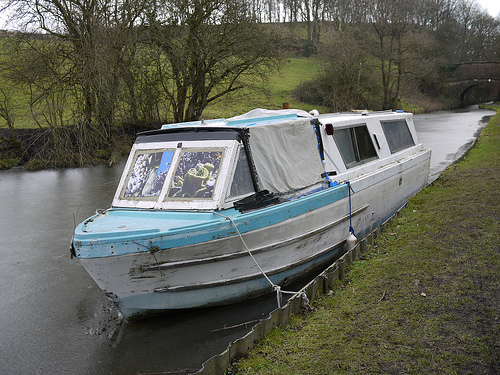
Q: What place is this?
A: It is a shore.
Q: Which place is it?
A: It is a shore.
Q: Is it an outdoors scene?
A: Yes, it is outdoors.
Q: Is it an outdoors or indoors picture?
A: It is outdoors.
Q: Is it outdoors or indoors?
A: It is outdoors.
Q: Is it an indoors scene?
A: No, it is outdoors.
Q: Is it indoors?
A: No, it is outdoors.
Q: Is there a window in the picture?
A: Yes, there is a window.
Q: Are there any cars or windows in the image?
A: Yes, there is a window.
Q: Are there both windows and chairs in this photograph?
A: No, there is a window but no chairs.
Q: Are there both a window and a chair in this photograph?
A: No, there is a window but no chairs.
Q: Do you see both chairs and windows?
A: No, there is a window but no chairs.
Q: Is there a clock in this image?
A: No, there are no clocks.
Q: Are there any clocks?
A: No, there are no clocks.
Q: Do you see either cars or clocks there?
A: No, there are no clocks or cars.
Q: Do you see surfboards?
A: No, there are no surfboards.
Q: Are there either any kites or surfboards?
A: No, there are no surfboards or kites.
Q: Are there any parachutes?
A: No, there are no parachutes.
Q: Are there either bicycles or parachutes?
A: No, there are no parachutes or bicycles.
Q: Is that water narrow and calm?
A: Yes, the water is narrow and calm.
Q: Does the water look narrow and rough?
A: No, the water is narrow but calm.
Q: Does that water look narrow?
A: Yes, the water is narrow.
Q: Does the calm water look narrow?
A: Yes, the water is narrow.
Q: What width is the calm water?
A: The water is narrow.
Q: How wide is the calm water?
A: The water is narrow.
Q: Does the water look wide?
A: No, the water is narrow.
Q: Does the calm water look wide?
A: No, the water is narrow.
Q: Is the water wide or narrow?
A: The water is narrow.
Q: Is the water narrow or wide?
A: The water is narrow.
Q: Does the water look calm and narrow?
A: Yes, the water is calm and narrow.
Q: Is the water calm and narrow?
A: Yes, the water is calm and narrow.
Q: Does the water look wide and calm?
A: No, the water is calm but narrow.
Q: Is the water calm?
A: Yes, the water is calm.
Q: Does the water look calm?
A: Yes, the water is calm.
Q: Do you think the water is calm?
A: Yes, the water is calm.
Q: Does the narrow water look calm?
A: Yes, the water is calm.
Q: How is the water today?
A: The water is calm.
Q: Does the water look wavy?
A: No, the water is calm.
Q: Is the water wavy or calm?
A: The water is calm.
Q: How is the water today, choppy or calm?
A: The water is calm.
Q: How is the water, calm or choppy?
A: The water is calm.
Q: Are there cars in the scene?
A: No, there are no cars.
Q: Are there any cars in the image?
A: No, there are no cars.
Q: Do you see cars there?
A: No, there are no cars.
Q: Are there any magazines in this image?
A: No, there are no magazines.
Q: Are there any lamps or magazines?
A: No, there are no magazines or lamps.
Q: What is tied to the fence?
A: The rope is tied to the fence.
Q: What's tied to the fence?
A: The rope is tied to the fence.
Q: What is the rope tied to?
A: The rope is tied to the fence.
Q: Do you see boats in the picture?
A: Yes, there is a boat.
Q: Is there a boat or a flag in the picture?
A: Yes, there is a boat.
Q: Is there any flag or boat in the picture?
A: Yes, there is a boat.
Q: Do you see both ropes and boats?
A: Yes, there are both a boat and a rope.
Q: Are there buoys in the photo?
A: No, there are no buoys.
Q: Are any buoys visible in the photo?
A: No, there are no buoys.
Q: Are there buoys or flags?
A: No, there are no buoys or flags.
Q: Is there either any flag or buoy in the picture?
A: No, there are no buoys or flags.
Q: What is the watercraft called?
A: The watercraft is a boat.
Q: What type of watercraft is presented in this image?
A: The watercraft is a boat.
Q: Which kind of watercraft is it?
A: The watercraft is a boat.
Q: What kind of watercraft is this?
A: This is a boat.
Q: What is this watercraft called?
A: This is a boat.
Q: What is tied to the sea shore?
A: The boat is tied to the sea shore.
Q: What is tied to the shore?
A: The boat is tied to the sea shore.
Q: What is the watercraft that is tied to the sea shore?
A: The watercraft is a boat.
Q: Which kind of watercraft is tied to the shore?
A: The watercraft is a boat.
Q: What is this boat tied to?
A: The boat is tied to the shore.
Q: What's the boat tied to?
A: The boat is tied to the shore.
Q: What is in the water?
A: The boat is in the water.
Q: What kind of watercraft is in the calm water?
A: The watercraft is a boat.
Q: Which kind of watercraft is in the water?
A: The watercraft is a boat.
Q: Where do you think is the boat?
A: The boat is in the water.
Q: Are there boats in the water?
A: Yes, there is a boat in the water.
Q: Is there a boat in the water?
A: Yes, there is a boat in the water.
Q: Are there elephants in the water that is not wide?
A: No, there is a boat in the water.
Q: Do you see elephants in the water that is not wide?
A: No, there is a boat in the water.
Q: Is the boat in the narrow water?
A: Yes, the boat is in the water.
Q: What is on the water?
A: The boat is on the water.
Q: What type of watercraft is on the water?
A: The watercraft is a boat.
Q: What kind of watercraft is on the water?
A: The watercraft is a boat.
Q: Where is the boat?
A: The boat is on the water.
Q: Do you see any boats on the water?
A: Yes, there is a boat on the water.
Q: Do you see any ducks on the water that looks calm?
A: No, there is a boat on the water.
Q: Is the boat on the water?
A: Yes, the boat is on the water.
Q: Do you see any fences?
A: Yes, there is a fence.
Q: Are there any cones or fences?
A: Yes, there is a fence.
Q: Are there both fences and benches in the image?
A: No, there is a fence but no benches.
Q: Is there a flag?
A: No, there are no flags.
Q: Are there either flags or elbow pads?
A: No, there are no flags or elbow pads.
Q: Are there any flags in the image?
A: No, there are no flags.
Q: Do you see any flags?
A: No, there are no flags.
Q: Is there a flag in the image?
A: No, there are no flags.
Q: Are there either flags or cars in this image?
A: No, there are no flags or cars.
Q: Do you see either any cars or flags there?
A: No, there are no flags or cars.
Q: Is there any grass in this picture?
A: Yes, there is grass.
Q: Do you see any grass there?
A: Yes, there is grass.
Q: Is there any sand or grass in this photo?
A: Yes, there is grass.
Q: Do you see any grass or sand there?
A: Yes, there is grass.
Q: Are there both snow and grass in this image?
A: No, there is grass but no snow.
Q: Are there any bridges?
A: Yes, there is a bridge.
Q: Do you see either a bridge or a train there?
A: Yes, there is a bridge.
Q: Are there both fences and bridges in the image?
A: Yes, there are both a bridge and a fence.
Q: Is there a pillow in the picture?
A: No, there are no pillows.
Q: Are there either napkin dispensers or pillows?
A: No, there are no pillows or napkin dispensers.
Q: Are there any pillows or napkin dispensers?
A: No, there are no pillows or napkin dispensers.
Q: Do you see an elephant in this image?
A: No, there are no elephants.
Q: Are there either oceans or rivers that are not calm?
A: No, there is a river but it is calm.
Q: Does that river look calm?
A: Yes, the river is calm.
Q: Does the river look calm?
A: Yes, the river is calm.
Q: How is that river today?
A: The river is calm.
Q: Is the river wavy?
A: No, the river is calm.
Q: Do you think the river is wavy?
A: No, the river is calm.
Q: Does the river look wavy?
A: No, the river is calm.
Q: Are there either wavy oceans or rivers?
A: No, there is a river but it is calm.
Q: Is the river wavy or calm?
A: The river is calm.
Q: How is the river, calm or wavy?
A: The river is calm.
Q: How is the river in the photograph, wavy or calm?
A: The river is calm.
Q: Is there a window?
A: Yes, there is a window.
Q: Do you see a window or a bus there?
A: Yes, there is a window.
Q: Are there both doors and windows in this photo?
A: No, there is a window but no doors.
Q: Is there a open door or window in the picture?
A: Yes, there is an open window.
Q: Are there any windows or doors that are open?
A: Yes, the window is open.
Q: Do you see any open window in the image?
A: Yes, there is an open window.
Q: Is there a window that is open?
A: Yes, there is a window that is open.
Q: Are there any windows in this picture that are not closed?
A: Yes, there is a open window.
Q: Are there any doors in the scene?
A: No, there are no doors.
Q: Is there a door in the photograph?
A: No, there are no doors.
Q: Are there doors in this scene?
A: No, there are no doors.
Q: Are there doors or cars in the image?
A: No, there are no doors or cars.